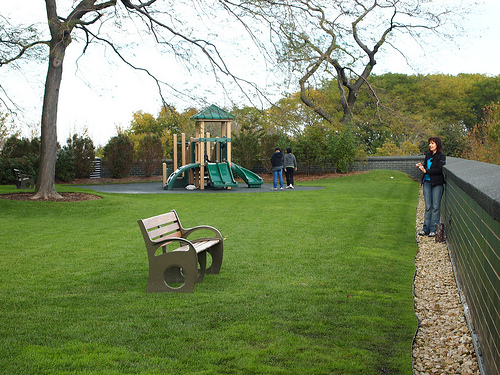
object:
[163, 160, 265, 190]
slides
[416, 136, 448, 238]
woman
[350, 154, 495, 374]
wall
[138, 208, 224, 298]
bench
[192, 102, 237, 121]
playground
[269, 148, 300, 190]
people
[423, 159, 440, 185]
blue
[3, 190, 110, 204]
gravel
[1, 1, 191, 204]
tree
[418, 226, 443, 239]
shoes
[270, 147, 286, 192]
man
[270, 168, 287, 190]
jeans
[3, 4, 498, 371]
park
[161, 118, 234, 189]
gilded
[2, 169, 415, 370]
grass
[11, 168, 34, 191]
another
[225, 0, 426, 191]
trees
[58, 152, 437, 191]
fence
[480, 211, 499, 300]
bricks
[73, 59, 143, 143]
clear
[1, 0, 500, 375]
outside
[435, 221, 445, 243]
bag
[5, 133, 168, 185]
bushes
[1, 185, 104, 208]
circular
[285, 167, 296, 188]
pants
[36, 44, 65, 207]
trunk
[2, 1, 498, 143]
clouds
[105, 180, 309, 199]
walk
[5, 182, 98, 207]
bud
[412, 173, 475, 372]
border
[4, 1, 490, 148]
background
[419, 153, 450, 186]
jacket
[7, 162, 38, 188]
bench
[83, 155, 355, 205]
area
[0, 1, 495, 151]
sky